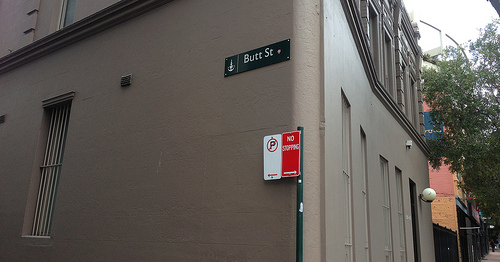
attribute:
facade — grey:
[95, 31, 229, 250]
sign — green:
[217, 34, 292, 81]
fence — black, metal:
[433, 221, 460, 261]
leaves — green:
[425, 48, 478, 104]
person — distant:
[487, 227, 497, 252]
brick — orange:
[436, 201, 451, 217]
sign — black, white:
[220, 36, 294, 84]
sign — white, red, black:
[256, 124, 306, 184]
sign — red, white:
[258, 127, 303, 184]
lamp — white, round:
[416, 183, 440, 203]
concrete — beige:
[302, 10, 437, 260]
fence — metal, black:
[429, 223, 460, 259]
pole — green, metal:
[290, 123, 308, 259]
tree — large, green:
[426, 29, 498, 260]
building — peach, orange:
[426, 161, 464, 261]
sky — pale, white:
[404, 2, 494, 71]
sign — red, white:
[240, 123, 319, 185]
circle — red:
[244, 123, 311, 180]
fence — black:
[442, 197, 496, 250]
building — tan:
[26, 9, 384, 227]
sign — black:
[213, 33, 320, 92]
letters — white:
[214, 30, 293, 71]